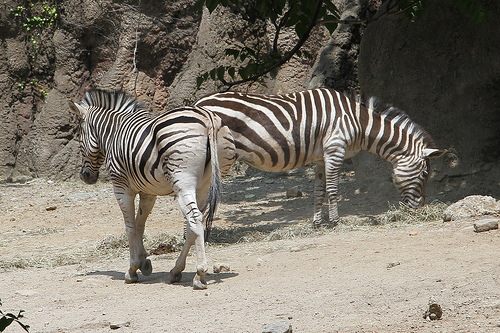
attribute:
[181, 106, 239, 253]
tail — hairy, zebra's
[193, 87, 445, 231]
zebras — black and white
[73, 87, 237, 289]
zebras — black and white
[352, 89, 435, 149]
mane — striped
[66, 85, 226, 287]
zebra — standing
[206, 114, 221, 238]
tail — White and gray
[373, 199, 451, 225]
grass — dry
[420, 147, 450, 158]
ear — pointed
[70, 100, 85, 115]
ear — pointed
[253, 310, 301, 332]
rock — light colored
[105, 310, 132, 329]
rock — light colored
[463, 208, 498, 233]
rock — light colored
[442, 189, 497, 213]
rock — light colored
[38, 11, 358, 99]
rock wall — dark, natural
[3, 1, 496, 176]
wall — stone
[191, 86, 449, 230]
zebra — standing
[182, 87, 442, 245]
zebra — grazing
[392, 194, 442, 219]
grass — dried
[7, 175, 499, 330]
hill — rocky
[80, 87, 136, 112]
mane — White and black